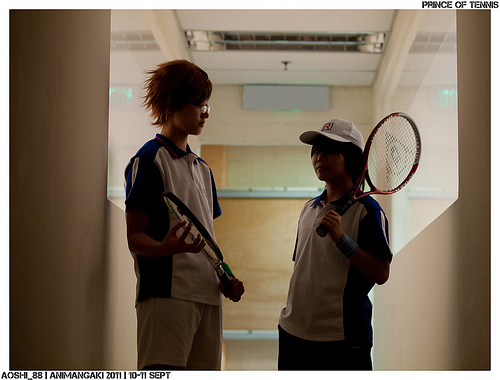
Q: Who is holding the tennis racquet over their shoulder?
A: The boy on the left.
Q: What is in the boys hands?
A: A tennis racquet.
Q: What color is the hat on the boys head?
A: White.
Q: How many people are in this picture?
A: Two.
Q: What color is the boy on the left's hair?
A: Red.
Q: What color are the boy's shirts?
A: White and blue.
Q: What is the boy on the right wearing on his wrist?
A: A wrist band.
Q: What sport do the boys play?
A: Tennis.